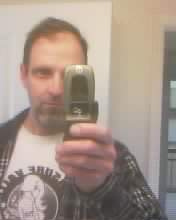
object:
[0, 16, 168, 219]
man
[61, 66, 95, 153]
cell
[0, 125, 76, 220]
t-shirt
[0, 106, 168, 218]
shirt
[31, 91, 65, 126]
beard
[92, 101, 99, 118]
antenna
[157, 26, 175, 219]
doorway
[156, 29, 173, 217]
edge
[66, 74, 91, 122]
back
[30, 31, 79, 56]
hairline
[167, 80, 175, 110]
windows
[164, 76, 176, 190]
room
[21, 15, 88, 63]
hair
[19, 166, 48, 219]
character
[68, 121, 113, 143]
finger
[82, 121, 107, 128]
edge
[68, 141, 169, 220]
sleeve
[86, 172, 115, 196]
edge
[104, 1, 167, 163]
wall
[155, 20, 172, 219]
room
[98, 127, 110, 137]
part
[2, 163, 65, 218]
part